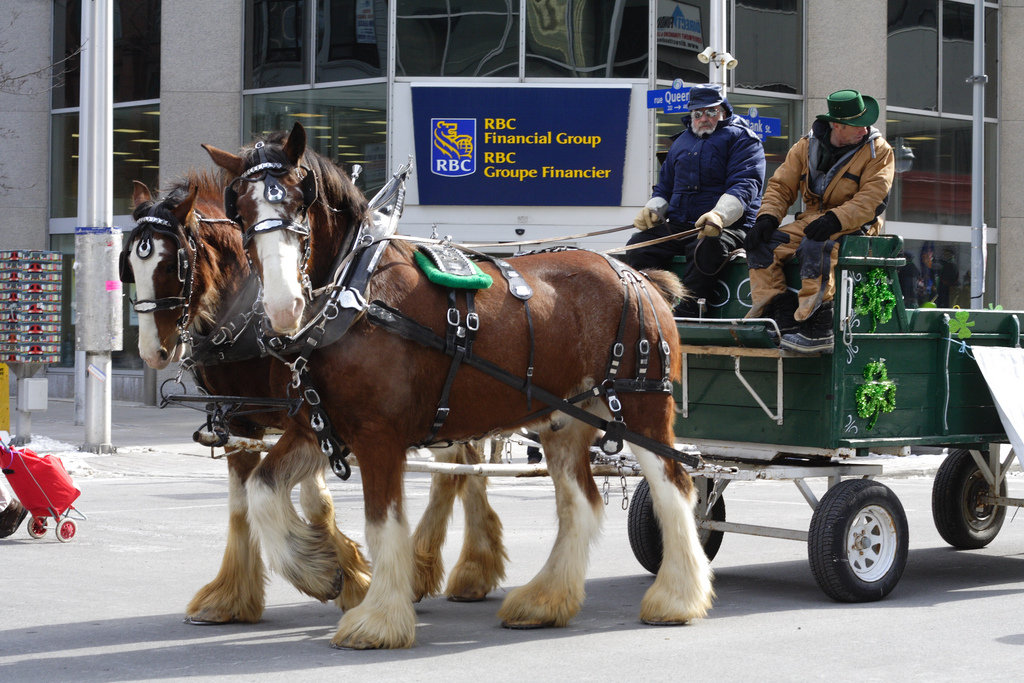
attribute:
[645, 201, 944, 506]
wagon — green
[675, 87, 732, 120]
hat — blue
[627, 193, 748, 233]
gloves — white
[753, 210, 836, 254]
gloves — black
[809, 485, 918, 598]
wheel — black, round